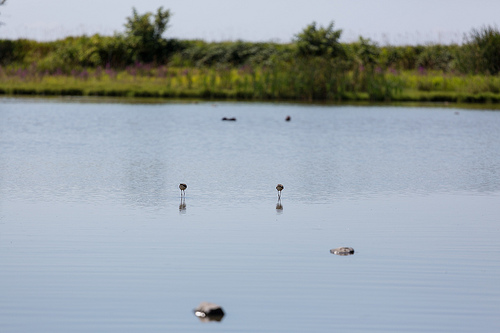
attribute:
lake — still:
[18, 113, 423, 298]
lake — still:
[17, 75, 493, 314]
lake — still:
[14, 69, 459, 318]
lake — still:
[14, 103, 461, 317]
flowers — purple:
[19, 57, 184, 83]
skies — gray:
[6, 3, 466, 52]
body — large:
[365, 137, 457, 239]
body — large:
[31, 125, 130, 235]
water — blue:
[24, 87, 467, 292]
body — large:
[217, 13, 289, 45]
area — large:
[24, 108, 147, 227]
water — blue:
[24, 83, 430, 273]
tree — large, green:
[118, 6, 188, 67]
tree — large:
[118, 6, 170, 63]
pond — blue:
[64, 144, 169, 296]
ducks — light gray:
[119, 148, 373, 282]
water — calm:
[43, 125, 461, 314]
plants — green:
[1, 3, 499, 103]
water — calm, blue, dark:
[1, 92, 499, 331]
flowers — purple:
[16, 65, 171, 75]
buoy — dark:
[178, 180, 187, 209]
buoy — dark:
[275, 182, 284, 209]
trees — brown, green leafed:
[290, 19, 343, 59]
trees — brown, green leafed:
[451, 31, 498, 73]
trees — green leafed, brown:
[41, 33, 110, 73]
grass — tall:
[3, 67, 498, 97]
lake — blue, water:
[0, 95, 499, 329]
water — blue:
[400, 174, 485, 324]